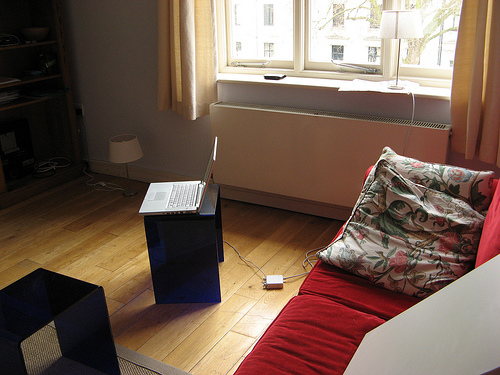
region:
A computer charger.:
[224, 232, 326, 294]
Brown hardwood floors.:
[4, 172, 346, 372]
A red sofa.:
[226, 167, 498, 373]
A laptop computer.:
[137, 134, 221, 216]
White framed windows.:
[219, 0, 460, 85]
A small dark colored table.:
[140, 177, 228, 304]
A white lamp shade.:
[106, 132, 146, 165]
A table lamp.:
[372, 5, 424, 94]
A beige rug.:
[1, 287, 188, 374]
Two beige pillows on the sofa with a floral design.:
[324, 146, 492, 303]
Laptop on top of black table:
[137, 133, 221, 215]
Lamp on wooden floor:
[105, 130, 147, 197]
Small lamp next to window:
[377, 4, 421, 94]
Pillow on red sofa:
[317, 158, 480, 293]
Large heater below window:
[206, 99, 455, 212]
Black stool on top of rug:
[0, 265, 126, 374]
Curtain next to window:
[155, 0, 218, 121]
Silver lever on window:
[327, 58, 380, 78]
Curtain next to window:
[451, 0, 498, 169]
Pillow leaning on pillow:
[312, 158, 482, 295]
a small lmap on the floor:
[106, 130, 140, 197]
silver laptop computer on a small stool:
[138, 135, 220, 213]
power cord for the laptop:
[224, 234, 324, 291]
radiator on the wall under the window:
[208, 100, 450, 228]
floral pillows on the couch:
[316, 147, 492, 299]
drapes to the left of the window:
[153, 2, 215, 119]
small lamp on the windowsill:
[379, 5, 426, 93]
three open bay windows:
[215, 2, 460, 88]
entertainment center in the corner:
[1, 0, 90, 205]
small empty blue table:
[1, 264, 124, 374]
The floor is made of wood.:
[1, 170, 341, 373]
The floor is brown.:
[1, 170, 344, 373]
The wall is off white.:
[66, 0, 211, 190]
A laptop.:
[137, 133, 217, 214]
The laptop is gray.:
[140, 134, 218, 215]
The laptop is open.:
[138, 133, 221, 213]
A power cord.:
[223, 235, 325, 290]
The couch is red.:
[234, 162, 499, 372]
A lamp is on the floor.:
[103, 127, 147, 199]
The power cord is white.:
[224, 238, 328, 290]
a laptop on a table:
[47, 81, 294, 373]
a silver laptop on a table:
[93, 120, 262, 315]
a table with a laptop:
[92, 122, 277, 346]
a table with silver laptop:
[114, 126, 260, 338]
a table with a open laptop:
[94, 104, 258, 305]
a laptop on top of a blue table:
[103, 112, 271, 332]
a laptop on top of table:
[93, 111, 261, 314]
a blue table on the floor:
[92, 123, 264, 332]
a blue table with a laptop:
[122, 111, 300, 325]